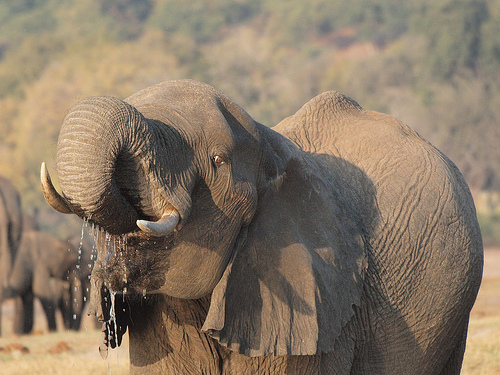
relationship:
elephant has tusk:
[67, 69, 487, 374] [133, 210, 189, 237]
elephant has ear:
[67, 69, 487, 374] [240, 163, 376, 362]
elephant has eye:
[67, 69, 487, 374] [207, 150, 228, 171]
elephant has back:
[67, 69, 487, 374] [253, 88, 462, 180]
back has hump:
[253, 88, 462, 180] [297, 87, 369, 128]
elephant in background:
[4, 225, 92, 321] [5, 130, 41, 158]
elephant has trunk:
[67, 69, 487, 374] [54, 91, 179, 199]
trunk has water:
[54, 91, 179, 199] [76, 235, 135, 297]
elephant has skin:
[67, 69, 487, 374] [294, 87, 485, 304]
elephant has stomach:
[67, 69, 487, 374] [160, 332, 214, 368]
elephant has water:
[67, 69, 487, 374] [76, 235, 135, 297]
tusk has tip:
[133, 210, 189, 237] [132, 219, 148, 229]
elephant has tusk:
[67, 69, 487, 374] [33, 160, 57, 208]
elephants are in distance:
[4, 225, 92, 321] [8, 110, 45, 141]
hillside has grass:
[399, 62, 468, 102] [39, 359, 59, 369]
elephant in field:
[67, 69, 487, 374] [474, 322, 500, 349]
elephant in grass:
[67, 69, 487, 374] [39, 359, 59, 369]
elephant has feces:
[67, 69, 487, 374] [41, 334, 74, 359]